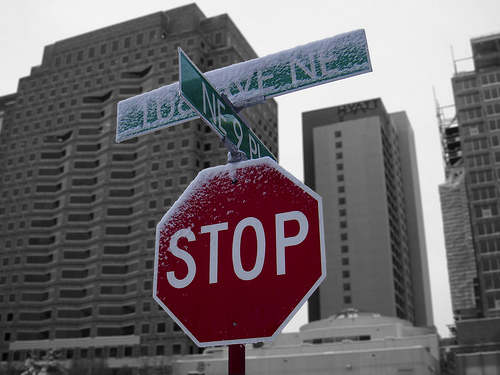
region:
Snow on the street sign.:
[120, 95, 157, 109]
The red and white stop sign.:
[153, 155, 322, 374]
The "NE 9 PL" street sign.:
[176, 46, 282, 160]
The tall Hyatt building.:
[301, 95, 438, 374]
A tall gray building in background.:
[0, 0, 278, 374]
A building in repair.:
[435, 33, 499, 374]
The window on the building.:
[64, 250, 89, 258]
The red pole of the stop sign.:
[227, 343, 243, 374]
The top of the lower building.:
[300, 308, 427, 341]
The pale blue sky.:
[391, 48, 428, 107]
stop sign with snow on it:
[152, 154, 328, 346]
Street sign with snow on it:
[108, 26, 375, 146]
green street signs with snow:
[114, 25, 375, 169]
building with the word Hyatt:
[296, 95, 435, 333]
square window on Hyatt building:
[332, 127, 344, 138]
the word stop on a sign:
[165, 206, 309, 288]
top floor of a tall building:
[37, 0, 258, 61]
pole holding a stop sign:
[226, 340, 248, 373]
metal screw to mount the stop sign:
[230, 320, 238, 327]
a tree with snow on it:
[22, 348, 69, 374]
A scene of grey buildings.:
[0, 2, 498, 372]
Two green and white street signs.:
[111, 29, 388, 156]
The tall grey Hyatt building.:
[299, 95, 437, 320]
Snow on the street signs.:
[216, 59, 270, 76]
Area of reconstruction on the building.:
[436, 96, 463, 223]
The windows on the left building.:
[3, 152, 146, 190]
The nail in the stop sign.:
[228, 320, 240, 327]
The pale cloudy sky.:
[2, 2, 82, 27]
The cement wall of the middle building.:
[353, 203, 387, 258]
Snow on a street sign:
[111, 29, 368, 139]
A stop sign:
[151, 155, 327, 350]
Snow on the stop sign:
[146, 152, 273, 250]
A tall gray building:
[302, 91, 422, 323]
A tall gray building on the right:
[436, 33, 499, 373]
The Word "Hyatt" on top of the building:
[326, 94, 387, 121]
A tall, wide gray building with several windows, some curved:
[1, 0, 276, 372]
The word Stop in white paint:
[163, 206, 310, 291]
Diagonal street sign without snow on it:
[181, 46, 281, 165]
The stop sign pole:
[209, 346, 275, 373]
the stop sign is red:
[100, 160, 346, 366]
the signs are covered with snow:
[95, 56, 422, 204]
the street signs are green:
[82, 38, 373, 158]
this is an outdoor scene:
[30, 65, 403, 339]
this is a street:
[36, 10, 490, 358]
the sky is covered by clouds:
[383, 31, 418, 67]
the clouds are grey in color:
[409, 30, 426, 75]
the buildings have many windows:
[6, 83, 151, 349]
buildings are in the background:
[30, 5, 483, 370]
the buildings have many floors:
[41, 32, 498, 311]